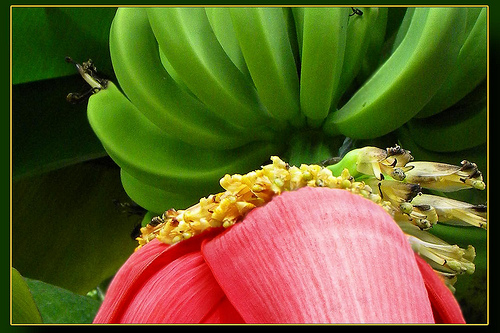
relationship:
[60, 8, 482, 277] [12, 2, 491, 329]
bananas on plant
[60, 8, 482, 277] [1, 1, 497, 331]
bananas on photo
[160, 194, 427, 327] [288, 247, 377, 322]
red petals with lines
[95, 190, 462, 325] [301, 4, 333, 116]
plant with bananas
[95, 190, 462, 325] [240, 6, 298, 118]
plant with bananas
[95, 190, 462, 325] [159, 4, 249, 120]
plant with bananas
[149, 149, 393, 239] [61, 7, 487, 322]
seeds on plant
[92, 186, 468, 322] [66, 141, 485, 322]
leaves on plant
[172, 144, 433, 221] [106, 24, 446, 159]
flower under bananas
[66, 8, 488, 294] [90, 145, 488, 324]
bananas above flower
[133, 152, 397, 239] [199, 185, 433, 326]
yellow top on red leaves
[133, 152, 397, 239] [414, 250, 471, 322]
yellow top on red leaves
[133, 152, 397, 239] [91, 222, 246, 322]
yellow top on red leaves